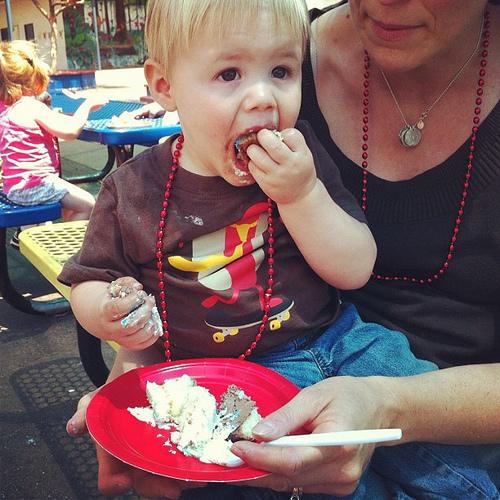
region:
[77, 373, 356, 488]
The plate in the woman's hand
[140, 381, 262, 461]
The cake on the plate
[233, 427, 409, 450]
The fork on the plate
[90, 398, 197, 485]
The color of the plate is red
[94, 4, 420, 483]
The child is eating cake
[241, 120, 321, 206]
The hand of the child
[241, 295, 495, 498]
The child is wearing jeans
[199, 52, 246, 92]
The eye of the child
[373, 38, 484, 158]
The woman is wearing a necklace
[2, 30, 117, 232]
A young girl is sitting on the bench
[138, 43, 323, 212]
Little boy eating cake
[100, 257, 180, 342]
frosting over hand of little boy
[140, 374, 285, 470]
piece of cake on red plate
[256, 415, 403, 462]
plastic white fork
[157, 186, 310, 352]
red bead necklace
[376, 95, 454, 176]
a silver locket necklace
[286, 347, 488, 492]
little boy wearing jeans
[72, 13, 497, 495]
little boy sitting on lady's lap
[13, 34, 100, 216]
little girl with red hair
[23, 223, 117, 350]
yellow bench with holes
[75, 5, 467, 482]
toddler eating cake with his hands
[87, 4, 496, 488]
woman holding plate of cake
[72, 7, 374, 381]
toddler is wearing a brown shirt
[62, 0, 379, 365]
toddler has blonde hair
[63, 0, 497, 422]
toddler and woman are both wearing red beaded necklaces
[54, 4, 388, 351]
toddler boy has cake in both hands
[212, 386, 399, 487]
white plastic fork in woman's hand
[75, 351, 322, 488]
red paper plate has cake on it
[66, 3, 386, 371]
boy is eating chocolate cake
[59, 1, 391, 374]
boy has cake icing on his hands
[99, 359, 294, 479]
Ice cream in red bowl.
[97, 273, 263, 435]
Ice cream by the handful.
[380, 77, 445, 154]
Locket necklace with charm.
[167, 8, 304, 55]
Blonde bangs.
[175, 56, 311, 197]
Boy eats ice cream from hand.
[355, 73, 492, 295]
A red bead necklace.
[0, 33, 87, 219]
Sitting on a metal bench.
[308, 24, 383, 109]
A collar bone.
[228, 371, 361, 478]
Thumb and index finger holding white utensil.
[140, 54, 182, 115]
A boys ear.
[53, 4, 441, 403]
Baby eating handful of cake.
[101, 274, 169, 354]
Baby holding handful of cake.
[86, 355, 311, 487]
Red plate with cake.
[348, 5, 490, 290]
Woman wearing red beads around neck.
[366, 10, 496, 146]
Woman wearing silver necklace around neck.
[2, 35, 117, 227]
Little girl sitting at table in background.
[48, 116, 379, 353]
Little boy wearing brown t-shirt with cartoon on front.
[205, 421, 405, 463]
White plastic food on cake plate.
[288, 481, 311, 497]
Woman wearing wedding ring on finger.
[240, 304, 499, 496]
Little boy dressed in blue jeans.